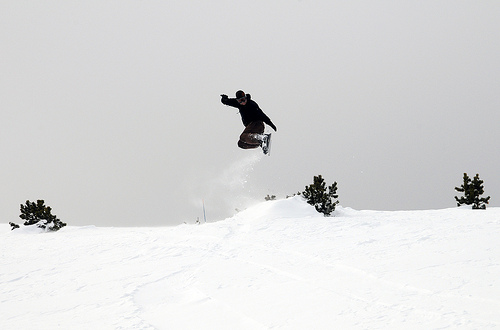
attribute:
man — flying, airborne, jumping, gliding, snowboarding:
[220, 89, 277, 149]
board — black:
[266, 133, 272, 155]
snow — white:
[180, 153, 264, 202]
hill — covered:
[1, 209, 498, 329]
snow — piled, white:
[238, 193, 354, 220]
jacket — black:
[222, 93, 272, 125]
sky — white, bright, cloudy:
[2, 1, 499, 226]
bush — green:
[288, 174, 340, 219]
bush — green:
[454, 173, 493, 209]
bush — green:
[9, 199, 64, 234]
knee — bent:
[241, 134, 247, 141]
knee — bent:
[238, 140, 244, 147]